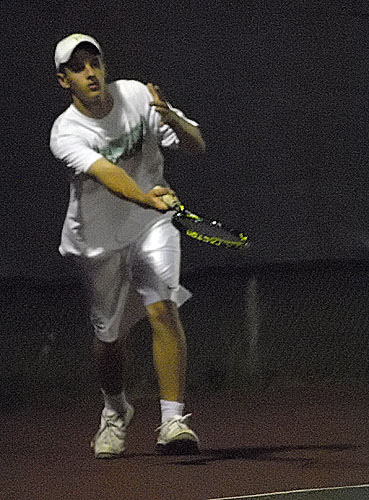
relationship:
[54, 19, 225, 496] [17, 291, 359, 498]
player on court